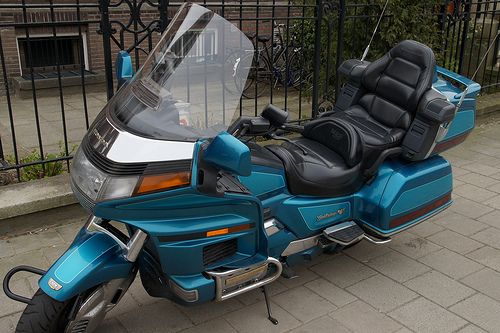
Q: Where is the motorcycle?
A: In front of the gate.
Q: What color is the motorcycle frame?
A: Blue.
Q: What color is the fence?
A: Black.